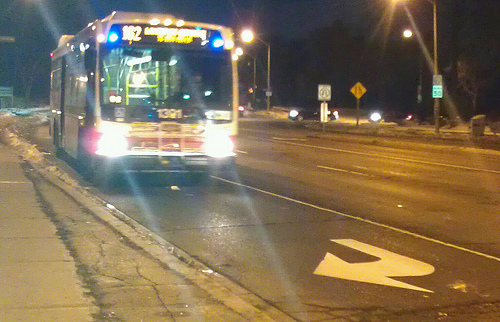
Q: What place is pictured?
A: It is a road.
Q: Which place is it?
A: It is a road.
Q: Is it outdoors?
A: Yes, it is outdoors.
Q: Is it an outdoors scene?
A: Yes, it is outdoors.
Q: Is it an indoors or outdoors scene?
A: It is outdoors.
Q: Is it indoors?
A: No, it is outdoors.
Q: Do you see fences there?
A: No, there are no fences.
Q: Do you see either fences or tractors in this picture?
A: No, there are no fences or tractors.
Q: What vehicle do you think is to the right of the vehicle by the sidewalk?
A: The vehicle is a car.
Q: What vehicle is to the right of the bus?
A: The vehicle is a car.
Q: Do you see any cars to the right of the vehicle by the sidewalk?
A: Yes, there is a car to the right of the bus.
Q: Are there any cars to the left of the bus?
A: No, the car is to the right of the bus.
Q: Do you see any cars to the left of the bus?
A: No, the car is to the right of the bus.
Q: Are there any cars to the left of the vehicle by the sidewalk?
A: No, the car is to the right of the bus.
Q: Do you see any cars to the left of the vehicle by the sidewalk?
A: No, the car is to the right of the bus.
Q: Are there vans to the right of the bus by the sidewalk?
A: No, there is a car to the right of the bus.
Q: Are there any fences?
A: No, there are no fences.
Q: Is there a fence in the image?
A: No, there are no fences.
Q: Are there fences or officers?
A: No, there are no fences or officers.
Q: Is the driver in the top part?
A: Yes, the driver is in the top of the image.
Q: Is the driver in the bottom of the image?
A: No, the driver is in the top of the image.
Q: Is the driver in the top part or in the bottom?
A: The driver is in the top of the image.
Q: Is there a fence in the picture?
A: No, there are no fences.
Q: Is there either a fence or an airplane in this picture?
A: No, there are no fences or airplanes.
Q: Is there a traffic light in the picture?
A: No, there are no traffic lights.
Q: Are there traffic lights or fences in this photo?
A: No, there are no traffic lights or fences.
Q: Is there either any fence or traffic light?
A: No, there are no traffic lights or fences.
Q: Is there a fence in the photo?
A: No, there are no fences.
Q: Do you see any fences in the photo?
A: No, there are no fences.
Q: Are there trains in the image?
A: No, there are no trains.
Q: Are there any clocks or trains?
A: No, there are no trains or clocks.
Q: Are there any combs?
A: No, there are no combs.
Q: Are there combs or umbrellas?
A: No, there are no combs or umbrellas.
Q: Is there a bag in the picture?
A: No, there are no bags.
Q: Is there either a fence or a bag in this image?
A: No, there are no bags or fences.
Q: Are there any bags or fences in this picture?
A: No, there are no bags or fences.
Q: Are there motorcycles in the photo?
A: No, there are no motorcycles.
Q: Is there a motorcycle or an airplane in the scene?
A: No, there are no motorcycles or airplanes.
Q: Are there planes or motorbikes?
A: No, there are no motorbikes or planes.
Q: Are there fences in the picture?
A: No, there are no fences.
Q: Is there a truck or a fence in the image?
A: No, there are no fences or trucks.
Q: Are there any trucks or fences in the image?
A: No, there are no fences or trucks.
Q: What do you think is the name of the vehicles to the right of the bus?
A: The vehicles are cars.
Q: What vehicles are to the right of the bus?
A: The vehicles are cars.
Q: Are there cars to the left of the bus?
A: No, the cars are to the right of the bus.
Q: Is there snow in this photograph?
A: Yes, there is snow.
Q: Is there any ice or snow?
A: Yes, there is snow.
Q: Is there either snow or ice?
A: Yes, there is snow.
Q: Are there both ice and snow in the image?
A: No, there is snow but no ice.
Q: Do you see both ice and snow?
A: No, there is snow but no ice.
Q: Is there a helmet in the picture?
A: No, there are no helmets.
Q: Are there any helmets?
A: No, there are no helmets.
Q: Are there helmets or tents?
A: No, there are no helmets or tents.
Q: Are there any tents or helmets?
A: No, there are no helmets or tents.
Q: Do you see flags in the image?
A: No, there are no flags.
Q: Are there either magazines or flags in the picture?
A: No, there are no flags or magazines.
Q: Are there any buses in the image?
A: Yes, there is a bus.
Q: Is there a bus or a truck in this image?
A: Yes, there is a bus.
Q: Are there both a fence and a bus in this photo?
A: No, there is a bus but no fences.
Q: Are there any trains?
A: No, there are no trains.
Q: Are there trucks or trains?
A: No, there are no trains or trucks.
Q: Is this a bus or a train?
A: This is a bus.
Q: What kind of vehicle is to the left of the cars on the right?
A: The vehicle is a bus.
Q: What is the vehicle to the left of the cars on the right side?
A: The vehicle is a bus.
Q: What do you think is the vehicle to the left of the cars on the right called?
A: The vehicle is a bus.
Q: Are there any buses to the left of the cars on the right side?
A: Yes, there is a bus to the left of the cars.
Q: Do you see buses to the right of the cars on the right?
A: No, the bus is to the left of the cars.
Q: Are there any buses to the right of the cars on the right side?
A: No, the bus is to the left of the cars.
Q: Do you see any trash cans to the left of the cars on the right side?
A: No, there is a bus to the left of the cars.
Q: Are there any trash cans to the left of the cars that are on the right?
A: No, there is a bus to the left of the cars.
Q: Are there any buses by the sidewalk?
A: Yes, there is a bus by the sidewalk.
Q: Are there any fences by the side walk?
A: No, there is a bus by the side walk.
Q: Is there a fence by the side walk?
A: No, there is a bus by the side walk.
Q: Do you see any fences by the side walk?
A: No, there is a bus by the side walk.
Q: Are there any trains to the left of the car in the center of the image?
A: No, there is a bus to the left of the car.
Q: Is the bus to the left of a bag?
A: No, the bus is to the left of a car.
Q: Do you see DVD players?
A: No, there are no DVD players.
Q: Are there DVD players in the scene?
A: No, there are no DVD players.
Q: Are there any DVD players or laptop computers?
A: No, there are no DVD players or laptop computers.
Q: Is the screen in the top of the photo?
A: Yes, the screen is in the top of the image.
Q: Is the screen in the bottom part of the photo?
A: No, the screen is in the top of the image.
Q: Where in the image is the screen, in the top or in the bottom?
A: The screen is in the top of the image.